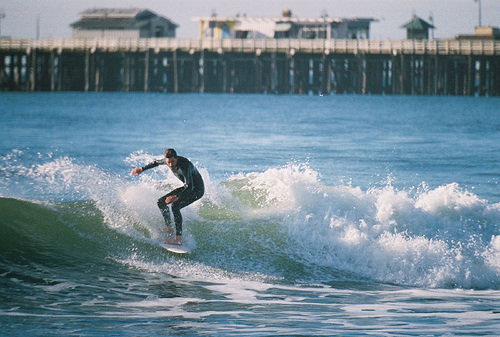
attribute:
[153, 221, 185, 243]
feet — bare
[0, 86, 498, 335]
water — light blue, clean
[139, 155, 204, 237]
wet suit — black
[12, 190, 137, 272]
wave — great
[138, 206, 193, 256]
surfboard — white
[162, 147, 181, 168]
hair — brown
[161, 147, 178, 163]
hair — dark